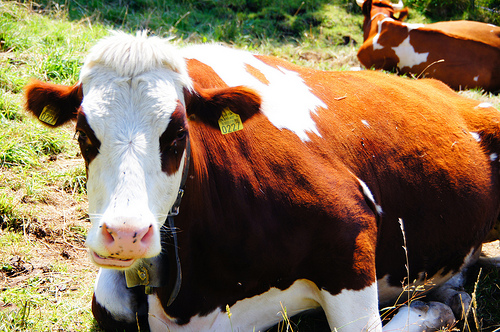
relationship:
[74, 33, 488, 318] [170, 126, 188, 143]
cow has eye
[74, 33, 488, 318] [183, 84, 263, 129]
cow has ear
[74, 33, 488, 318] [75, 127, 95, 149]
cow has eye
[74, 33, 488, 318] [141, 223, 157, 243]
cow has nostril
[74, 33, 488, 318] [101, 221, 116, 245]
cow has nostril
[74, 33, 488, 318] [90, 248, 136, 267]
cow has mouth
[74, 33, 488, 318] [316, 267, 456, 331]
cow has leg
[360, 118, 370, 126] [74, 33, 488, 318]
spot on side of cow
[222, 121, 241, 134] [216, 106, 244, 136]
number stamped on tag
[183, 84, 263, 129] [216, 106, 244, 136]
ear with tag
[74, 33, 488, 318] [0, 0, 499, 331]
cow standing on grass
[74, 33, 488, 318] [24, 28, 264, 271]
cow has head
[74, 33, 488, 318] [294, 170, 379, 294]
cow has shoulder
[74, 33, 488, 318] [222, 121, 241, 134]
cow has number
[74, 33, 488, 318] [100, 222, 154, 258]
cow has nose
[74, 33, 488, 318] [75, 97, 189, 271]
cow has face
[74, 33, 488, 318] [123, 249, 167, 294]
cow wears bell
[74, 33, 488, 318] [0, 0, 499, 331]
cow laying in grass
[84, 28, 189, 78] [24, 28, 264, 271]
fur on top of head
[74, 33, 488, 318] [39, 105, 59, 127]
cow has tag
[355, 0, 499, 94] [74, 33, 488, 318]
cow behind cow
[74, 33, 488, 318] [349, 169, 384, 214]
cow has spot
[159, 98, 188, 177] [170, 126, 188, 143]
fur around eye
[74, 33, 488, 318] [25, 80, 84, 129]
cow has ear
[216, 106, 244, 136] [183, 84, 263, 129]
tag hanging on ear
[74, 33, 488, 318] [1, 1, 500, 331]
cow sitting on hill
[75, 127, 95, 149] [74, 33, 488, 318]
eye of cow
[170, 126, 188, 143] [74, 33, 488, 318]
eye of cow